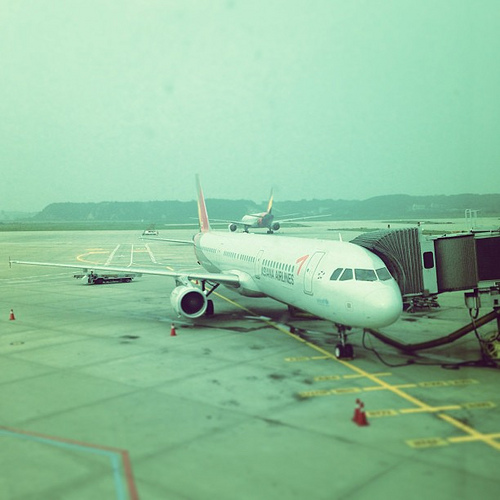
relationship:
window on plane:
[280, 260, 288, 270] [0, 173, 404, 363]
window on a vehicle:
[329, 265, 339, 287] [22, 172, 399, 347]